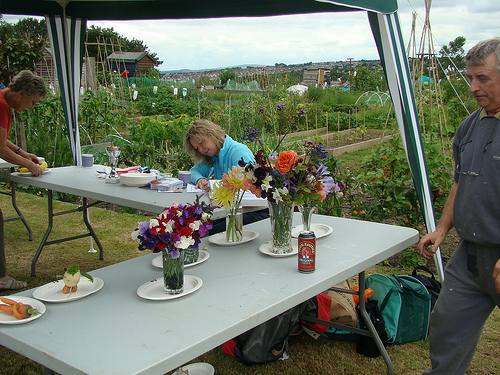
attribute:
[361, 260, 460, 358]
bag — green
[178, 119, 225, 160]
head — WOMAN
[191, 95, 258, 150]
hair — curly